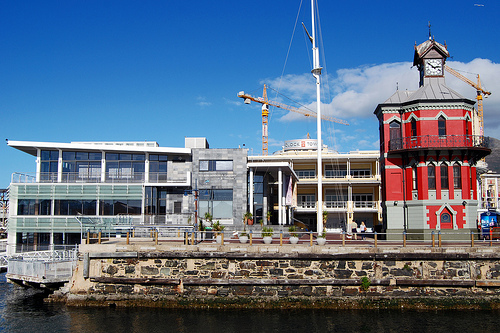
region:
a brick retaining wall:
[133, 237, 296, 327]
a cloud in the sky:
[265, 65, 371, 128]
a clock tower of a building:
[410, 34, 451, 96]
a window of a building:
[433, 111, 453, 142]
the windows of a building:
[422, 161, 470, 193]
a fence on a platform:
[76, 226, 176, 245]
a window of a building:
[195, 157, 239, 169]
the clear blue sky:
[76, 40, 123, 91]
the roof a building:
[1, 132, 193, 160]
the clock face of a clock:
[427, 58, 443, 73]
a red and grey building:
[370, 28, 488, 243]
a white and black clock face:
[417, 52, 446, 79]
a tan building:
[251, 136, 381, 233]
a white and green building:
[5, 137, 177, 260]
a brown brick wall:
[66, 247, 497, 308]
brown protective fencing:
[77, 226, 499, 243]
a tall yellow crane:
[236, 82, 351, 151]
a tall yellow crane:
[442, 57, 491, 139]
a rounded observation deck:
[383, 126, 488, 161]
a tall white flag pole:
[309, 0, 324, 245]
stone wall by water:
[53, 245, 498, 317]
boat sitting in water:
[8, 255, 77, 289]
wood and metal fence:
[86, 228, 498, 246]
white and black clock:
[424, 57, 444, 75]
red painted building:
[381, 103, 478, 230]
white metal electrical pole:
[308, 0, 324, 238]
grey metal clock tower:
[416, 27, 448, 80]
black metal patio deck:
[391, 136, 494, 156]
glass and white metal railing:
[11, 175, 143, 200]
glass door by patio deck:
[391, 117, 403, 152]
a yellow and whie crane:
[228, 79, 359, 154]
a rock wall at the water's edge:
[58, 240, 497, 308]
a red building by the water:
[374, 83, 493, 247]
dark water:
[1, 273, 492, 331]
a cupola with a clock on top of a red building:
[406, 34, 456, 84]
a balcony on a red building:
[386, 129, 497, 155]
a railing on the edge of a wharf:
[80, 218, 499, 252]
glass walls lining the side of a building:
[31, 141, 176, 190]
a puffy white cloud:
[272, 47, 498, 135]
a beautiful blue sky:
[4, 2, 497, 180]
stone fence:
[69, 245, 499, 317]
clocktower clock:
[405, 21, 453, 77]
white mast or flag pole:
[293, 4, 335, 240]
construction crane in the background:
[230, 77, 349, 154]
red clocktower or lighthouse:
[369, 17, 484, 237]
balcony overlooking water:
[0, 239, 86, 291]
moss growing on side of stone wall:
[352, 271, 381, 296]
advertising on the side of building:
[477, 205, 499, 234]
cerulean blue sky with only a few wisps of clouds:
[2, 2, 239, 122]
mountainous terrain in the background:
[483, 137, 498, 166]